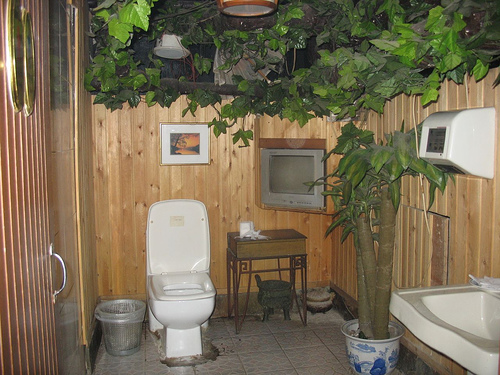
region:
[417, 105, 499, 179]
Air hand dryer in the bathroom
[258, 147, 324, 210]
Television built into wall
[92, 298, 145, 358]
Trash receptacle in the bathroom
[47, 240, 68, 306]
Pull handle mounted to door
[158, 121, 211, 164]
Picture mounted on the wall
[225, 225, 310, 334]
Small table in the bathroom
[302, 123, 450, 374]
Potted plant sitting on the floor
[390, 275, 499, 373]
Bathroom sink hanging from wall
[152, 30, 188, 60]
Overhead light hanging from the ceiling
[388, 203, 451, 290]
Access door in bathroom wall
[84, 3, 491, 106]
green ivy on ceiling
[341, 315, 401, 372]
blue and white flower pot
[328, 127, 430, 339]
tree with green leaves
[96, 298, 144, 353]
grey metal trash can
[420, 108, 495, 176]
white metal hand dryer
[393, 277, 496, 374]
white ceramic bathroom sink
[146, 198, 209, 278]
white plastic toilet lid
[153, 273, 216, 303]
white ceramic toilet seat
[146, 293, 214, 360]
white ceramic toilet bowl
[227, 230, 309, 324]
brown table in bathroom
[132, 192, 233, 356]
this is a toilet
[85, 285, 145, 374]
this is a bucket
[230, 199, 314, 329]
a small table in the room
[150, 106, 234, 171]
a picture on the wall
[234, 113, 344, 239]
this is a television set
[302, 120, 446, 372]
this is a tree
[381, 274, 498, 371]
this is a sink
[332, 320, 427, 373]
this is a flower pot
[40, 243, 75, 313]
this is a door handle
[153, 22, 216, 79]
this is a lamp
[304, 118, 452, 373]
a tree in a blue and white pot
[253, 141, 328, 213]
the television is gray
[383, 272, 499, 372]
the sink is white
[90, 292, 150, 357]
a trash can beside the toilet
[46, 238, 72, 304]
the door handle is silver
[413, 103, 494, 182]
a white hand dryer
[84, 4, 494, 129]
leaves on the ceiling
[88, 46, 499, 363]
the walls are wooden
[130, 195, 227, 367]
the toilet is white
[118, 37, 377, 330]
This is a bathroom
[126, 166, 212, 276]
This is the lid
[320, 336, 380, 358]
This is a vase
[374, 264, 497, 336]
This is a sink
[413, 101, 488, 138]
This is a hand drier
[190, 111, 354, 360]
This is a table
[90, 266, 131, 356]
This is a trashcan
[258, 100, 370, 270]
This is a television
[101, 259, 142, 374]
The trashcan is silver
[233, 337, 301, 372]
This is grey tile